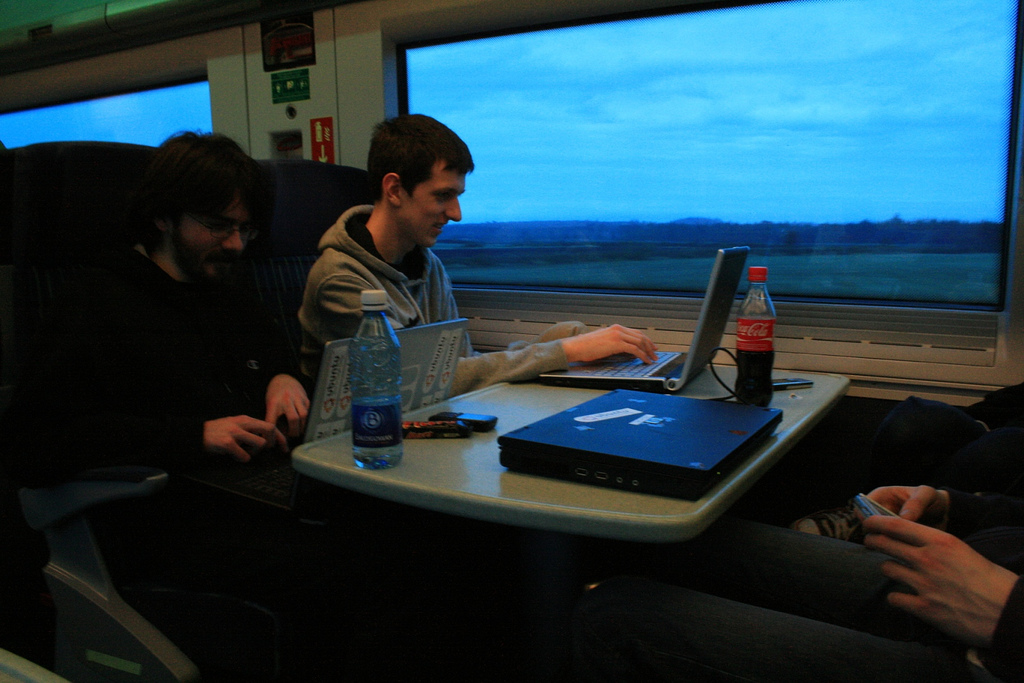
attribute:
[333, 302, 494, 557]
bottle — plastic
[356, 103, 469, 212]
hair — black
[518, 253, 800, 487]
laptop — black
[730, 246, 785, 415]
bottle — drink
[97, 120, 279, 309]
hair — black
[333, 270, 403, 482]
bottle — clear, water bottle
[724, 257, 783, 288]
lid — red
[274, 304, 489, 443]
laptop — silver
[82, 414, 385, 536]
lap — man's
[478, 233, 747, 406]
laptop — silver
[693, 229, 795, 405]
bottle — coca cola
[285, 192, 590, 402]
sweatshirt — grey, gray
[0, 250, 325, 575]
sweatshirt — black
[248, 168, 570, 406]
sweatshirt — gray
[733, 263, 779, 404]
soda bottle — Plastic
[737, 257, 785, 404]
soda bottle — Plastic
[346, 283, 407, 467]
water bottle — Plastic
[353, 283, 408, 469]
water bottle — Plastic